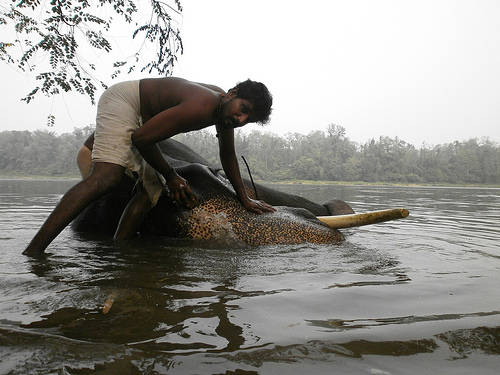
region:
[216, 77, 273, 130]
Dark haired man touching an elephant in the water.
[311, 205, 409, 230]
Tusk of an elephant.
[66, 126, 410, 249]
An elephant in the water.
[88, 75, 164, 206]
White cloth covering a dark haired mans middle section.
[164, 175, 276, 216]
Hands of a man touching an elephant.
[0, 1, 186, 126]
Thin leaves and branches over the man.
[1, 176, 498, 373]
Brown colored water.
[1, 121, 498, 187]
Tree line in the distance.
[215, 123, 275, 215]
Left arm of a dark skinned man.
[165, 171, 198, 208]
Right hand of a man with black hair.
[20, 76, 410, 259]
man bathing an elephant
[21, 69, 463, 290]
man and elephant in the river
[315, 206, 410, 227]
tusk on the elephant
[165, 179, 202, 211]
wash sponge in man's hand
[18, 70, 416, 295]
man bathing elephant in brown murky water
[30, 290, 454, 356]
brown murky water in the river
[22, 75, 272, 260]
man looking at cameraman while bathing an elephant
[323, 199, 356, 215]
back foot of an elephant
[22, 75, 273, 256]
man bending over washing an elephant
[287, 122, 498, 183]
trees on the side of the river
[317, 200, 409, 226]
a tusk on an elephant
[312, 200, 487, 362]
murky brown water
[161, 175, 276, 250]
a head of an elephant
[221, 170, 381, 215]
a leg of an elephant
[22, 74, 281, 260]
a handler of elephants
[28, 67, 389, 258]
a handler bathing an elephant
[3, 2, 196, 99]
branches hanging over a handler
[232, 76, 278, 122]
black hair on the head of a handler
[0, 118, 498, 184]
trees on the shoreline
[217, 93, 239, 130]
a beard on a handler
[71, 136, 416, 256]
Elephant in the water.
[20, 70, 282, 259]
Boy in the water.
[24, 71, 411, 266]
Boy in the water washing elephant.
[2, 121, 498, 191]
Trees in the background.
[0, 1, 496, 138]
Cloudy day in the sky.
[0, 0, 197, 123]
Tree hanging down next to boy.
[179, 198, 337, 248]
Speckles on the elephant's head.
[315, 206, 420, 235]
Elephant tusk sticking out of water.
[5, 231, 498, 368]
Water rippling next to elephant.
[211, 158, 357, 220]
Elephant leg sticking out of water.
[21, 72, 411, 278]
man standing over elephant lying in shallow water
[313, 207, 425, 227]
white elephant tusk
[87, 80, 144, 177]
white cloth wrapped around man's upper legs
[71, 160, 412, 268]
grey elephant lying on its side in body of water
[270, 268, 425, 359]
brown lake water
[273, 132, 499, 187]
tall trees and foliage in horizon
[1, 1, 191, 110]
green leaves on stems of tree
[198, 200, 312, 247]
pink speckled spots on elephant head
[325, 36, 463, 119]
overcast grey cloud sky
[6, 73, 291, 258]
man leaning over in water